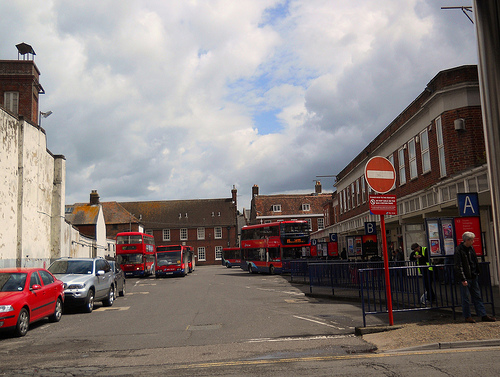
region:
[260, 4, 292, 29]
Small blue cloud patch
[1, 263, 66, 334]
Small white saloon car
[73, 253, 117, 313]
Big grey spacious car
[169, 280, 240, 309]
Smooth wide tarmacked road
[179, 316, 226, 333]
A small repaired pothole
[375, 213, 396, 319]
Long red colored pole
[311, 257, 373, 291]
Short metal bar fence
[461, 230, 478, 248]
Grey haired short man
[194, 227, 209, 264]
White colored large windows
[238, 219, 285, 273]
Double storied red bus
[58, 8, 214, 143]
sky filled with large white clouds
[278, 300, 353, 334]
white line painted onpavement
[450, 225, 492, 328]
man standing beside black guard railing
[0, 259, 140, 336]
row of parked vehicles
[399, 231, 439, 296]
man in green safety vest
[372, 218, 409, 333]
red metal sign pole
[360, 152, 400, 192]
metal red and white no entry sign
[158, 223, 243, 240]
row of white windows on side of building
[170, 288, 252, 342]
ground covered in grey pavement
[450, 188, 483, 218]
blue and white metal sign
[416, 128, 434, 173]
a window of a building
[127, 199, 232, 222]
the roof of a building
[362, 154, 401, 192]
a red and white sign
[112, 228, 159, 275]
a large red bus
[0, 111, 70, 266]
part of an old white building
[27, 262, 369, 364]
a paved roadway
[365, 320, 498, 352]
part of a sidewalk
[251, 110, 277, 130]
part of a blue sky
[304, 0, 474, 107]
a large white cloud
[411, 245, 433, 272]
a green safety vest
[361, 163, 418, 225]
do not enter traffic sign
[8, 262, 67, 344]
red car parked on street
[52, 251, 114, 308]
silver jeep parked on street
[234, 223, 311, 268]
red Double Decker Bus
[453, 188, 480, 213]
A sign on the building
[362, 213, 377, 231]
B sign on the building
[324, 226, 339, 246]
C sign on the building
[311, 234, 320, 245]
D sign on the building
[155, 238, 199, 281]
Bus next to another bus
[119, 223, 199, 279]
buses parked in the station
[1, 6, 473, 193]
The sky is very cloudy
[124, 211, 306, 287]
Many busses are parked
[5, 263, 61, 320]
The car is red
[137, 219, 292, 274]
The busses are red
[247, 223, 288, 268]
The busses have two stories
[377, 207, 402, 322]
The post is red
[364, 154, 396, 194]
The sign is red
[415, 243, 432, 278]
wearing a green jacket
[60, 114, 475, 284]
The buildings are red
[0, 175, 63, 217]
the wall is white and bare